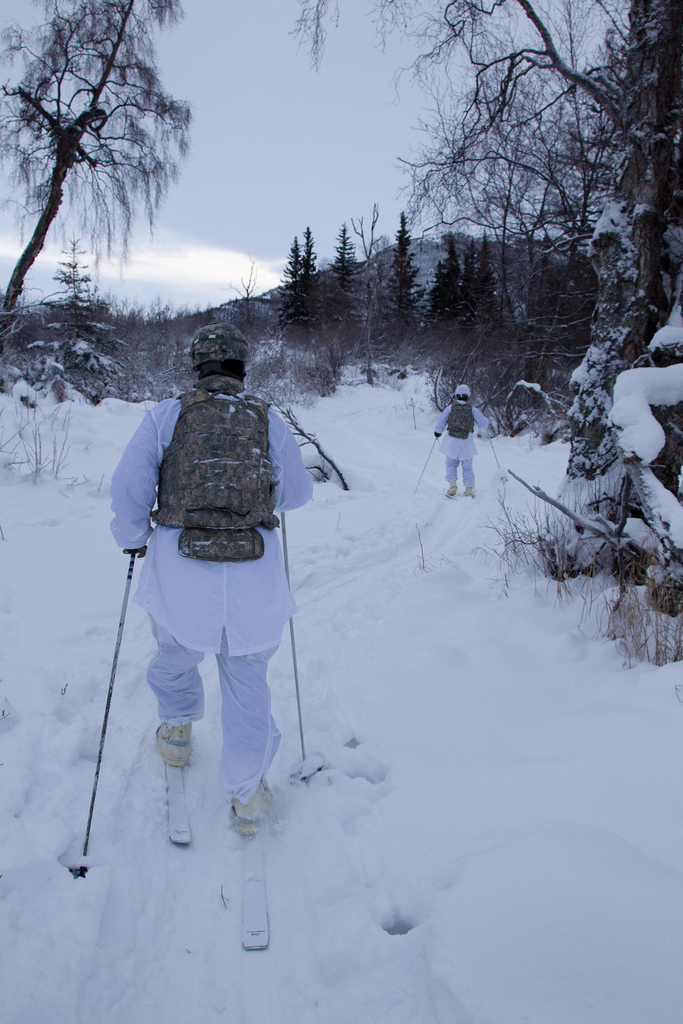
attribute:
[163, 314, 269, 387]
hat — camouflage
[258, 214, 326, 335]
tree — tall, green, needle filled, pine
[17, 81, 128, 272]
tree — tall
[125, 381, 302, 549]
back pack — camouflage, colored 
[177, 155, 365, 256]
sky — hazy, cloud filled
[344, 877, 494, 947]
print — foot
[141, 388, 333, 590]
backpack — camouflage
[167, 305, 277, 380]
helmet — camouflage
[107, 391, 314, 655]
jacket — white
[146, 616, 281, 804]
pants — white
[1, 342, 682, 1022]
snow — white, cold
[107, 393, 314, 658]
coat — white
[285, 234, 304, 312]
tree — evergreen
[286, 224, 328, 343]
tree — evergreen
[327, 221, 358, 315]
tree — evergreen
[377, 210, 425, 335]
tree — evergreen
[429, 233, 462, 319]
tree — evergreen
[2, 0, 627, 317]
sky — hazy, gray